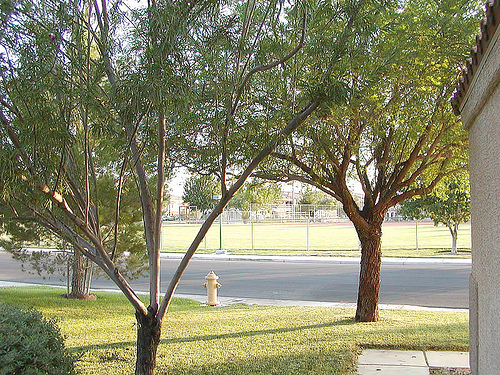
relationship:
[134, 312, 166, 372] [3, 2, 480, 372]
tree trunk in photo